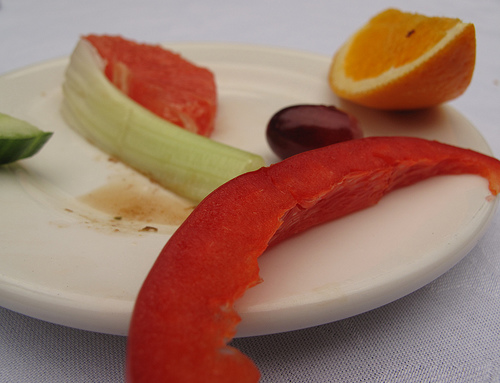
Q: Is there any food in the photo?
A: Yes, there is food.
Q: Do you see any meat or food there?
A: Yes, there is food.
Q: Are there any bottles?
A: No, there are no bottles.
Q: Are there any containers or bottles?
A: No, there are no bottles or containers.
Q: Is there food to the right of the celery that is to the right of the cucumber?
A: Yes, there is food to the right of the celery.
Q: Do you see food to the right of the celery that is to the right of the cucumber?
A: Yes, there is food to the right of the celery.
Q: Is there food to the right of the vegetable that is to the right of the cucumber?
A: Yes, there is food to the right of the celery.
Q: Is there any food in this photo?
A: Yes, there is food.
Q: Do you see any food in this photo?
A: Yes, there is food.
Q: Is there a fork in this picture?
A: No, there are no forks.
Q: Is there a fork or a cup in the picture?
A: No, there are no forks or cups.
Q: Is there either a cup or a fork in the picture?
A: No, there are no forks or cups.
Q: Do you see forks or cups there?
A: No, there are no forks or cups.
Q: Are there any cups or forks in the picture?
A: No, there are no forks or cups.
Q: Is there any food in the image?
A: Yes, there is food.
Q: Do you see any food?
A: Yes, there is food.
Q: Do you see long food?
A: Yes, there is long food.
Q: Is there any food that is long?
A: Yes, there is food that is long.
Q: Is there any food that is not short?
A: Yes, there is long food.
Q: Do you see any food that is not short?
A: Yes, there is long food.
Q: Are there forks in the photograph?
A: No, there are no forks.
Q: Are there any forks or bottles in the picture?
A: No, there are no forks or bottles.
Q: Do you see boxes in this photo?
A: No, there are no boxes.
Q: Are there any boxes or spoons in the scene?
A: No, there are no boxes or spoons.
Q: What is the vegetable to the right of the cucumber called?
A: The vegetable is a celery.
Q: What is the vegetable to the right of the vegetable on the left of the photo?
A: The vegetable is a celery.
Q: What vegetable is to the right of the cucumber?
A: The vegetable is a celery.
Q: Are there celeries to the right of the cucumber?
A: Yes, there is a celery to the right of the cucumber.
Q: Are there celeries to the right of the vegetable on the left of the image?
A: Yes, there is a celery to the right of the cucumber.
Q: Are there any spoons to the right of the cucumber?
A: No, there is a celery to the right of the cucumber.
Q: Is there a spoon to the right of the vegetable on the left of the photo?
A: No, there is a celery to the right of the cucumber.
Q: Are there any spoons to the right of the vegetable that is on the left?
A: No, there is a celery to the right of the cucumber.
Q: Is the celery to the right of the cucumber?
A: Yes, the celery is to the right of the cucumber.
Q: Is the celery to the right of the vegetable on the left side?
A: Yes, the celery is to the right of the cucumber.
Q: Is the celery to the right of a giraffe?
A: No, the celery is to the right of the cucumber.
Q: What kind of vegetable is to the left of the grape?
A: The vegetable is a celery.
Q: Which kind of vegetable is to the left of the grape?
A: The vegetable is a celery.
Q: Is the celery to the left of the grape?
A: Yes, the celery is to the left of the grape.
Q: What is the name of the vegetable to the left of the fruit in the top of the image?
A: The vegetable is a celery.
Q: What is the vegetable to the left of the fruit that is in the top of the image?
A: The vegetable is a celery.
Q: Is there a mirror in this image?
A: No, there are no mirrors.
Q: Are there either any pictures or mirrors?
A: No, there are no mirrors or pictures.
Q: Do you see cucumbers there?
A: Yes, there is a cucumber.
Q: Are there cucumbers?
A: Yes, there is a cucumber.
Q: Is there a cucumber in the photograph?
A: Yes, there is a cucumber.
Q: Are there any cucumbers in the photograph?
A: Yes, there is a cucumber.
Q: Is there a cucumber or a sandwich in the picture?
A: Yes, there is a cucumber.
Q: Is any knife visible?
A: No, there are no knives.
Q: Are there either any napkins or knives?
A: No, there are no knives or napkins.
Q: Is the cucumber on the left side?
A: Yes, the cucumber is on the left of the image.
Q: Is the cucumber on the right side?
A: No, the cucumber is on the left of the image.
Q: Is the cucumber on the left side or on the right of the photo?
A: The cucumber is on the left of the image.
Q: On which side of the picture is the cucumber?
A: The cucumber is on the left of the image.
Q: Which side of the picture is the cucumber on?
A: The cucumber is on the left of the image.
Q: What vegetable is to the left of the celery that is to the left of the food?
A: The vegetable is a cucumber.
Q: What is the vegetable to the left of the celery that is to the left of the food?
A: The vegetable is a cucumber.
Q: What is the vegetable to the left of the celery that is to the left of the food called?
A: The vegetable is a cucumber.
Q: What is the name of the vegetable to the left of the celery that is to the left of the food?
A: The vegetable is a cucumber.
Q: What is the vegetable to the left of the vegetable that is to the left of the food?
A: The vegetable is a cucumber.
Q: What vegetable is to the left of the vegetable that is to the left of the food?
A: The vegetable is a cucumber.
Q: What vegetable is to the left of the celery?
A: The vegetable is a cucumber.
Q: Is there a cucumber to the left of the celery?
A: Yes, there is a cucumber to the left of the celery.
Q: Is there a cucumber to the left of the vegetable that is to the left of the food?
A: Yes, there is a cucumber to the left of the celery.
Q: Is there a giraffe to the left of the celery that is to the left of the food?
A: No, there is a cucumber to the left of the celery.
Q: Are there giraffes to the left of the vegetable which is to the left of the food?
A: No, there is a cucumber to the left of the celery.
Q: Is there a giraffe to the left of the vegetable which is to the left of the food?
A: No, there is a cucumber to the left of the celery.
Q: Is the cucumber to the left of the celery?
A: Yes, the cucumber is to the left of the celery.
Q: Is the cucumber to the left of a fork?
A: No, the cucumber is to the left of the celery.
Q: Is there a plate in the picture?
A: Yes, there is a plate.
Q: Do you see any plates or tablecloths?
A: Yes, there is a plate.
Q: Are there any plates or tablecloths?
A: Yes, there is a plate.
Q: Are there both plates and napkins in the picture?
A: No, there is a plate but no napkins.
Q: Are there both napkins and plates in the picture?
A: No, there is a plate but no napkins.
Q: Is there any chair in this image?
A: No, there are no chairs.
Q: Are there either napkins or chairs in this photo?
A: No, there are no chairs or napkins.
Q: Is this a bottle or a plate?
A: This is a plate.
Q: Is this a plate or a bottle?
A: This is a plate.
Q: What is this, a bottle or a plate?
A: This is a plate.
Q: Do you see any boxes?
A: No, there are no boxes.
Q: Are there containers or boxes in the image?
A: No, there are no boxes or containers.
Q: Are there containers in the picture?
A: No, there are no containers.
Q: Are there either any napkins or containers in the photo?
A: No, there are no containers or napkins.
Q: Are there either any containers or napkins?
A: No, there are no containers or napkins.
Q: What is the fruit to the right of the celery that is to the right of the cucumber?
A: The fruit is a grape.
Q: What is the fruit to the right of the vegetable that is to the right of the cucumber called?
A: The fruit is a grape.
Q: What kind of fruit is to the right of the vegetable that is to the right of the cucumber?
A: The fruit is a grape.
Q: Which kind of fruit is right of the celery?
A: The fruit is a grape.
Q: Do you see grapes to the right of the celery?
A: Yes, there is a grape to the right of the celery.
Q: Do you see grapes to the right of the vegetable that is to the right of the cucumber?
A: Yes, there is a grape to the right of the celery.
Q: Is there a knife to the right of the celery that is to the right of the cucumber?
A: No, there is a grape to the right of the celery.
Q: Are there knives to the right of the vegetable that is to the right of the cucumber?
A: No, there is a grape to the right of the celery.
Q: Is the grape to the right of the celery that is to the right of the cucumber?
A: Yes, the grape is to the right of the celery.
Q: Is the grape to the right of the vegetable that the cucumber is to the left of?
A: Yes, the grape is to the right of the celery.